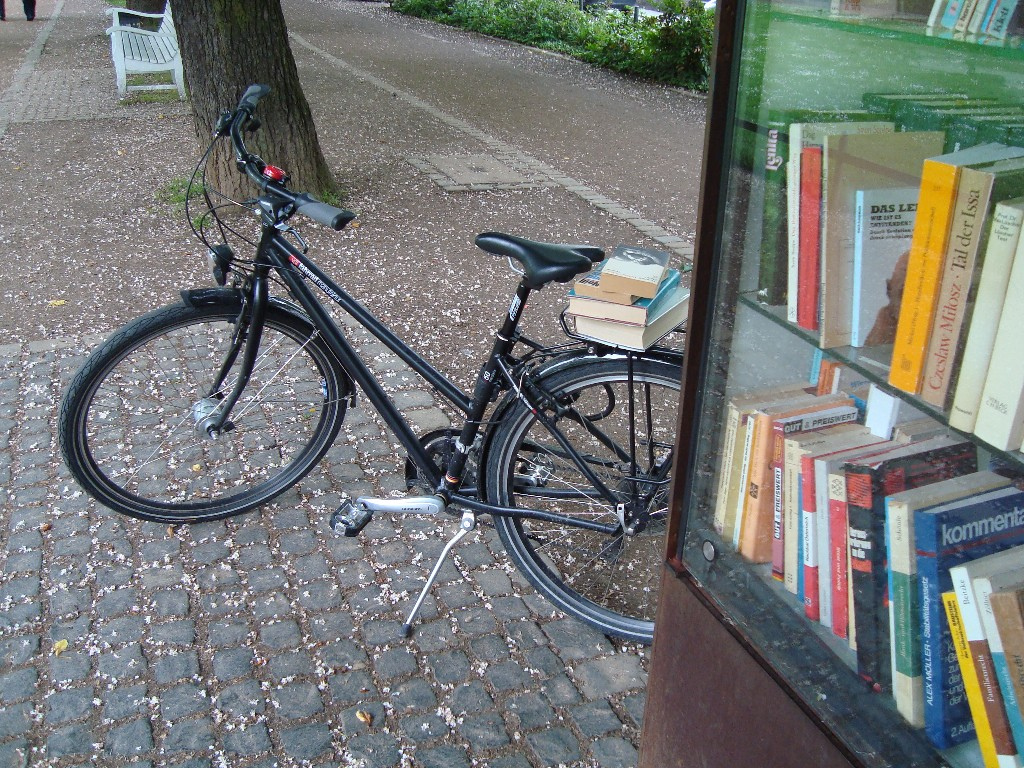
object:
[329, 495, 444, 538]
pedal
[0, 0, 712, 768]
leaves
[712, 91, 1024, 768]
books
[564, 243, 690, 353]
books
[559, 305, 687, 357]
rack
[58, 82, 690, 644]
bicycle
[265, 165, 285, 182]
light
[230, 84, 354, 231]
handlebar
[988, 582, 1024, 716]
book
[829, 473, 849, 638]
book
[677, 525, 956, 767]
shelf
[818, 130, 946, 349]
book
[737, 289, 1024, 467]
shelf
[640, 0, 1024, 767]
bookshelf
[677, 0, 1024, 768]
glass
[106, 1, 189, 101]
bench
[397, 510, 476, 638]
kickstand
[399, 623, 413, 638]
rubber tip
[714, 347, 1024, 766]
titles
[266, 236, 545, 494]
frame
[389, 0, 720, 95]
bushes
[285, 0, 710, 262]
pathway